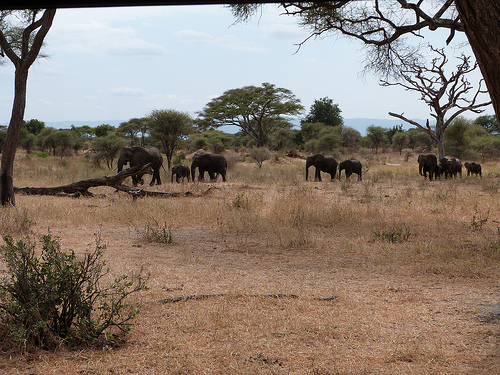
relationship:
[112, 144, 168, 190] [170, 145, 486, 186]
elephant leading herd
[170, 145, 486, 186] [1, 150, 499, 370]
herd walking through field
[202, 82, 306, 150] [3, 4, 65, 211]
tree has trunk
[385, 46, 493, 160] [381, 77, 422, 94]
tree has no leaves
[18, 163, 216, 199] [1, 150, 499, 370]
limb in field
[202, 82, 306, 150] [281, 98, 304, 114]
tree with leaves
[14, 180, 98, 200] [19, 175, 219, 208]
trunk has fallen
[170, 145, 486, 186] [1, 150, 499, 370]
herd in africa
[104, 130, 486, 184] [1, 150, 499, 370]
elephants walking in africa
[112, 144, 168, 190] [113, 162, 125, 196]
elephant has trunk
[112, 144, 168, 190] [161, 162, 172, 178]
elephant has tail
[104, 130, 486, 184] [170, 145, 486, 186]
elephants in group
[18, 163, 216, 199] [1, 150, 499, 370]
limb on ground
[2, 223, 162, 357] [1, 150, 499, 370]
bush on field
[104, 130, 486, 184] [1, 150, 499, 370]
elephants walk across field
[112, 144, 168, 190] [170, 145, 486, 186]
elephant leads herd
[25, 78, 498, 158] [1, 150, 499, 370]
trees in a field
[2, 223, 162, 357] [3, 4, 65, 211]
bush near tree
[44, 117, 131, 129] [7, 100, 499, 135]
mountain in distance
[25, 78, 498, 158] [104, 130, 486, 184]
trees behind elephants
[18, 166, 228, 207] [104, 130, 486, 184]
limb in front of elephants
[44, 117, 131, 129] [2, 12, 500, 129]
mountain in background